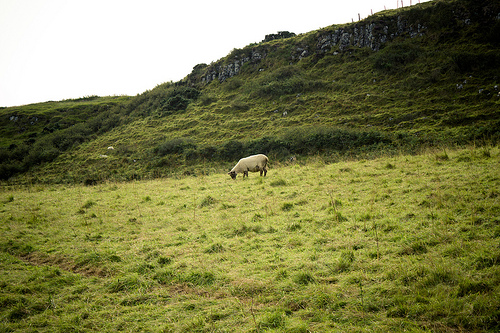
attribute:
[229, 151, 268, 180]
sheep —  white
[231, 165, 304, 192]
legs —  The front 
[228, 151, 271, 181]
lamb —  white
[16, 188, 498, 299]
field —  grass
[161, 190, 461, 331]
grass — tall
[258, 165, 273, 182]
legs — back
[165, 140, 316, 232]
animal — white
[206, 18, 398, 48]
cliff — face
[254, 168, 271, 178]
legs —  The hind